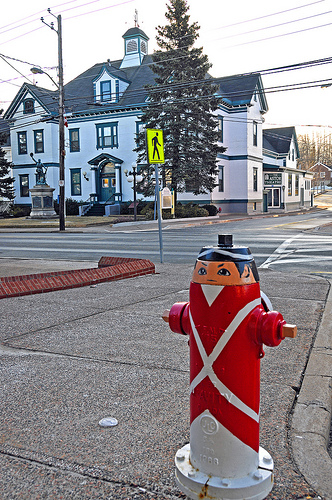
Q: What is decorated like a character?
A: The hydrant.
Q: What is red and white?
A: The hydrant.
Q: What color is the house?
A: Green and white.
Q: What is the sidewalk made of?
A: Cement.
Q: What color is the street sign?
A: Bright yellow.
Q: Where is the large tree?
A: In front of a building.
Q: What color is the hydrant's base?
A: White.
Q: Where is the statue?
A: In front of the house.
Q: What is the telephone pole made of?
A: Wood.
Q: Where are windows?
A: On a large house.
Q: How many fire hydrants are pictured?
A: One.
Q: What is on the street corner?
A: Utility pole.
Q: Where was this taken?
A: Street.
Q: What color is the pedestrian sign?
A: Yellow.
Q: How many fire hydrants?
A: 1.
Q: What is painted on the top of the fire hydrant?
A: Face.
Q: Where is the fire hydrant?
A: On the sidewalk.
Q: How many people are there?
A: 0.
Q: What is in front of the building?
A: Statue.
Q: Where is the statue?
A: In front of the building.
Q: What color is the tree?
A: Brown.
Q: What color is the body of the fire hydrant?
A: Red and white.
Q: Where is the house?
A: Opposite side of the road.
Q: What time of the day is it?
A: It's daytime.